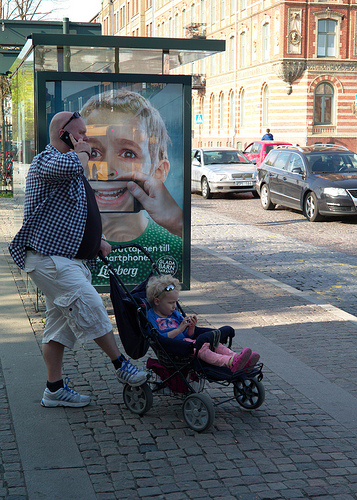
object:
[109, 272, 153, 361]
bag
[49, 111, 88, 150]
head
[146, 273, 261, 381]
baby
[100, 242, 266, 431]
stroller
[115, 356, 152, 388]
shoes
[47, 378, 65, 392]
socks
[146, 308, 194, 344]
shirt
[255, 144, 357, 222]
car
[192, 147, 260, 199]
car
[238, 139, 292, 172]
car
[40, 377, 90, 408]
tennis shoe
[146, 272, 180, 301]
hair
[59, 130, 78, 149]
cell phone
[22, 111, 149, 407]
man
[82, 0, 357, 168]
building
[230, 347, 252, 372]
shoe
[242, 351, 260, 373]
shoe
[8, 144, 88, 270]
shirt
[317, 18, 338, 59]
window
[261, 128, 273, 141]
person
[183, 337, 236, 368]
pants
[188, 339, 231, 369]
legs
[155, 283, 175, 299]
sunglasses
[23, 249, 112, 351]
khaki pants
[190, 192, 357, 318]
road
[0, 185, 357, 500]
sidewalk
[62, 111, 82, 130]
glasses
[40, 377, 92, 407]
feet